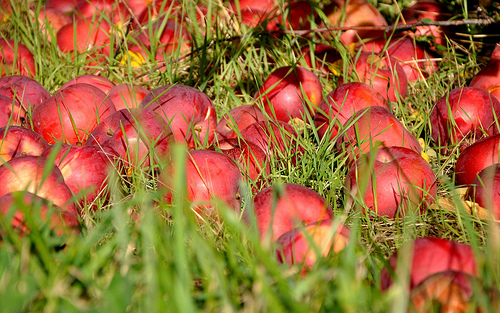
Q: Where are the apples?
A: On the ground.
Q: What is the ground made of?
A: Grass.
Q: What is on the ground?
A: Apples.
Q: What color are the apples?
A: Red.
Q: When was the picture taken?
A: Daytime.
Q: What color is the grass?
A: Green.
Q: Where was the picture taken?
A: At an orchard.